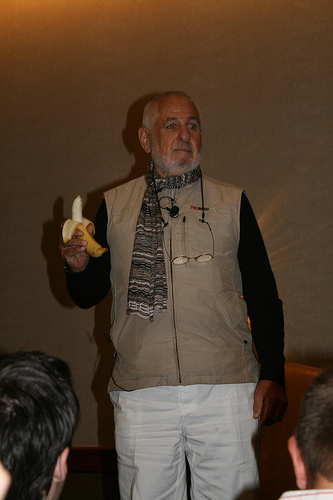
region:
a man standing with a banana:
[58, 85, 286, 498]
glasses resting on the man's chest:
[161, 217, 216, 265]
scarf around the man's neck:
[124, 160, 206, 321]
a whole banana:
[62, 193, 107, 256]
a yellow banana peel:
[61, 215, 107, 258]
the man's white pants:
[101, 373, 262, 498]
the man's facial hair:
[148, 129, 202, 176]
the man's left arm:
[237, 190, 286, 425]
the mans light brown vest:
[100, 174, 260, 389]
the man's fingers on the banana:
[61, 223, 94, 264]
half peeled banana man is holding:
[55, 192, 107, 262]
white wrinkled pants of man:
[97, 378, 267, 499]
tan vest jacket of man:
[102, 163, 263, 396]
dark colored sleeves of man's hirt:
[58, 172, 284, 381]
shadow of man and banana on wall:
[40, 191, 112, 310]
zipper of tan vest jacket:
[159, 189, 193, 385]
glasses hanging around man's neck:
[148, 164, 219, 267]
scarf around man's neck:
[125, 153, 222, 321]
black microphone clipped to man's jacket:
[158, 191, 183, 218]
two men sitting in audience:
[5, 346, 331, 492]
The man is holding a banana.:
[55, 89, 287, 310]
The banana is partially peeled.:
[58, 191, 111, 263]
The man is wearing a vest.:
[56, 85, 293, 432]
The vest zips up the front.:
[93, 165, 266, 398]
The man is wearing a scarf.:
[55, 87, 290, 434]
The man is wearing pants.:
[60, 85, 290, 498]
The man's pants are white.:
[62, 86, 283, 498]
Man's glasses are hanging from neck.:
[122, 85, 232, 276]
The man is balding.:
[128, 78, 212, 184]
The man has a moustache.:
[136, 86, 205, 178]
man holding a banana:
[40, 82, 252, 305]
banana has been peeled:
[57, 193, 106, 287]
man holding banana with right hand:
[40, 87, 268, 305]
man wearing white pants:
[85, 96, 280, 496]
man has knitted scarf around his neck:
[119, 88, 221, 312]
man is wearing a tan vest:
[82, 84, 281, 383]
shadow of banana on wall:
[40, 190, 68, 286]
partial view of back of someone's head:
[285, 373, 331, 479]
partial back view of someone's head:
[2, 353, 83, 499]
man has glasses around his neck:
[111, 85, 228, 271]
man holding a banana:
[33, 116, 209, 327]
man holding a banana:
[57, 178, 145, 327]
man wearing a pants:
[113, 371, 270, 491]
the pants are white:
[110, 381, 279, 498]